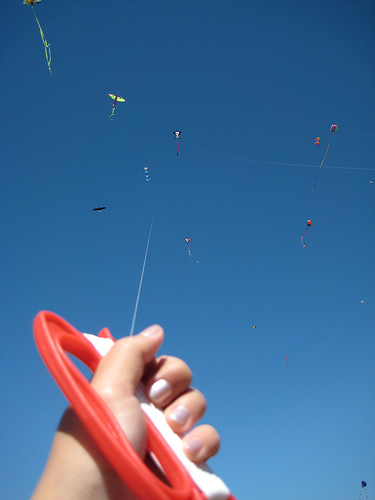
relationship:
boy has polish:
[28, 323, 220, 498] [185, 436, 202, 451]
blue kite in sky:
[141, 165, 154, 186] [1, 1, 373, 498]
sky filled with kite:
[1, 1, 373, 498] [309, 122, 340, 193]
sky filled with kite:
[1, 1, 373, 498] [298, 215, 315, 249]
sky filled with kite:
[1, 1, 373, 498] [105, 89, 127, 121]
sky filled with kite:
[1, 1, 373, 498] [169, 126, 185, 157]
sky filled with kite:
[1, 1, 373, 498] [92, 199, 108, 217]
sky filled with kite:
[1, 1, 373, 498] [20, 1, 56, 78]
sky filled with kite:
[1, 1, 373, 498] [181, 235, 200, 266]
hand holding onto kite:
[96, 343, 204, 411] [139, 159, 155, 183]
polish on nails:
[141, 323, 201, 454] [140, 324, 205, 453]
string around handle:
[131, 145, 173, 335] [34, 309, 239, 499]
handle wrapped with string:
[34, 309, 239, 499] [121, 303, 145, 319]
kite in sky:
[299, 219, 310, 248] [1, 1, 373, 498]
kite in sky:
[310, 123, 338, 194] [1, 1, 373, 498]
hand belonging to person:
[31, 321, 221, 498] [29, 321, 219, 498]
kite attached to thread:
[106, 90, 125, 124] [115, 110, 195, 165]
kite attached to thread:
[310, 123, 338, 194] [180, 137, 362, 170]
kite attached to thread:
[106, 90, 125, 124] [189, 244, 341, 446]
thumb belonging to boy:
[92, 323, 162, 384] [20, 325, 224, 498]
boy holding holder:
[20, 325, 224, 498] [32, 306, 253, 497]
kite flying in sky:
[106, 90, 125, 121] [1, 1, 373, 498]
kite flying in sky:
[22, 0, 54, 76] [1, 1, 373, 498]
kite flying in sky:
[172, 128, 182, 155] [1, 1, 373, 498]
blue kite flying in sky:
[142, 165, 151, 183] [1, 1, 373, 498]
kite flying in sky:
[359, 479, 367, 498] [1, 1, 373, 498]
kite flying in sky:
[310, 123, 338, 194] [1, 1, 373, 498]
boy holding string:
[28, 323, 220, 498] [122, 198, 178, 338]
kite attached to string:
[310, 123, 338, 194] [122, 198, 178, 338]